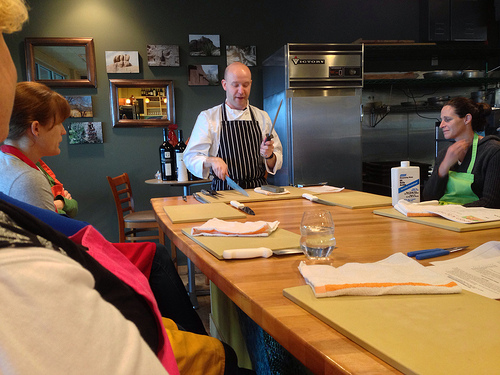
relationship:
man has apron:
[172, 51, 303, 199] [208, 102, 278, 182]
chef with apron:
[197, 54, 284, 139] [207, 104, 273, 182]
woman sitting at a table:
[412, 90, 492, 178] [305, 185, 493, 278]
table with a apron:
[305, 185, 493, 278] [433, 141, 476, 207]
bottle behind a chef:
[158, 128, 177, 182] [197, 38, 283, 178]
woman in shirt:
[1, 73, 75, 179] [2, 150, 61, 221]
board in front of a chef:
[196, 186, 321, 203] [203, 50, 283, 144]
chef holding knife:
[180, 62, 284, 193] [211, 167, 272, 212]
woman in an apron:
[420, 98, 500, 208] [420, 136, 497, 223]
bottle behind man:
[160, 129, 201, 191] [203, 58, 286, 168]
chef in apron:
[180, 62, 284, 193] [200, 109, 266, 174]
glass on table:
[290, 199, 339, 281] [256, 255, 307, 311]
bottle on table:
[385, 145, 434, 230] [330, 206, 377, 260]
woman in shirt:
[420, 98, 500, 208] [430, 140, 494, 180]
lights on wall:
[112, 84, 163, 124] [107, 133, 147, 186]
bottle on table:
[142, 115, 202, 200] [143, 187, 237, 248]